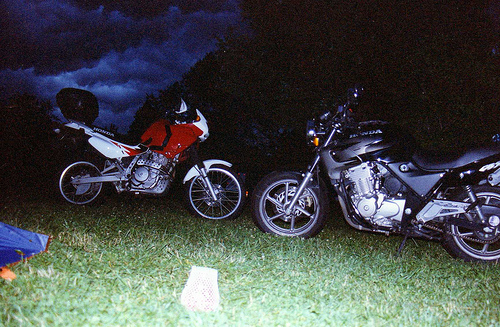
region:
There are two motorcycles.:
[35, 69, 495, 269]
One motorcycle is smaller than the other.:
[41, 75, 259, 227]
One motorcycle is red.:
[42, 80, 252, 230]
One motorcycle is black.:
[255, 78, 499, 265]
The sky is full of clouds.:
[5, 2, 255, 157]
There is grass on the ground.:
[6, 208, 496, 325]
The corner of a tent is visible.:
[2, 205, 57, 281]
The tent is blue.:
[0, 218, 59, 283]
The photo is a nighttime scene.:
[2, 0, 497, 175]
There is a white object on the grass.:
[165, 256, 243, 318]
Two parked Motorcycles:
[40, 80, 496, 260]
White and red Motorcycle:
[45, 75, 240, 220]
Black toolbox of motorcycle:
[51, 80, 97, 121]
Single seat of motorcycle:
[410, 141, 490, 166]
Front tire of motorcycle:
[175, 160, 240, 215]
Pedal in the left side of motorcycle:
[385, 210, 410, 235]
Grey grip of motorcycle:
[311, 80, 369, 120]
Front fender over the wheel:
[180, 150, 230, 175]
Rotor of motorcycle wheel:
[270, 190, 302, 220]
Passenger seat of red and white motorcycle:
[90, 120, 140, 148]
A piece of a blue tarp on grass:
[1, 207, 52, 274]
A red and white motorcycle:
[50, 81, 245, 219]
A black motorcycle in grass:
[251, 75, 496, 266]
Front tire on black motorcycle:
[255, 172, 327, 237]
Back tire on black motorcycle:
[448, 186, 496, 261]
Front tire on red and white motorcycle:
[187, 156, 239, 222]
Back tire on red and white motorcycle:
[60, 158, 102, 204]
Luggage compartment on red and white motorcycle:
[56, 85, 98, 122]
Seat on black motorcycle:
[415, 140, 496, 166]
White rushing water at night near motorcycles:
[1, 1, 248, 124]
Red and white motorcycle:
[41, 70, 246, 229]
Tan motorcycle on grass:
[11, 66, 493, 323]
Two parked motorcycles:
[45, 65, 497, 256]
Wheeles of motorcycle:
[55, 160, 498, 253]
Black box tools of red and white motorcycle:
[52, 80, 102, 126]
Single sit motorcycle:
[408, 141, 495, 169]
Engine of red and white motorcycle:
[120, 146, 176, 192]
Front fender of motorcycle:
[176, 151, 234, 181]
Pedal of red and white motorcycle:
[117, 165, 133, 191]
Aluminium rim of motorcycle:
[263, 175, 320, 235]